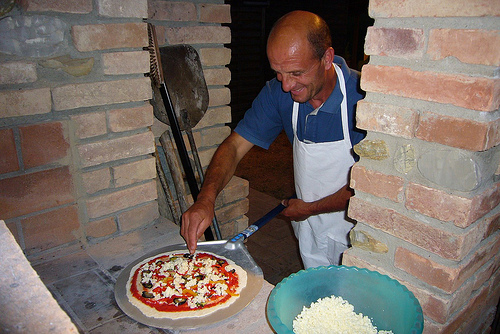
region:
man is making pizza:
[196, 29, 393, 321]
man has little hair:
[245, 10, 395, 87]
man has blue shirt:
[245, 87, 312, 157]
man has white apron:
[230, 62, 367, 282]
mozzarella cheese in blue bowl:
[281, 273, 398, 331]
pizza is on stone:
[135, 244, 228, 331]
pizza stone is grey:
[120, 236, 240, 332]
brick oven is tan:
[0, 10, 130, 235]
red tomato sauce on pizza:
[135, 261, 205, 332]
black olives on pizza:
[126, 243, 225, 304]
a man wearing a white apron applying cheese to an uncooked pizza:
[178, 9, 365, 264]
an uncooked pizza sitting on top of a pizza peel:
[124, 248, 249, 320]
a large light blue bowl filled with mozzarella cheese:
[266, 264, 425, 332]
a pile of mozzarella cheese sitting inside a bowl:
[292, 292, 390, 332]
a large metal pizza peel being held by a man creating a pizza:
[113, 200, 283, 329]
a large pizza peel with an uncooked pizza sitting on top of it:
[111, 205, 283, 328]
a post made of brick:
[343, 0, 498, 332]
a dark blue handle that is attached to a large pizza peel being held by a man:
[254, 196, 299, 228]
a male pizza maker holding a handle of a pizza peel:
[178, 9, 361, 266]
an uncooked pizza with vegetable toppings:
[127, 247, 248, 318]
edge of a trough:
[272, 280, 306, 316]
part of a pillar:
[387, 182, 438, 248]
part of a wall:
[28, 170, 85, 244]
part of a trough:
[327, 252, 368, 294]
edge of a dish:
[215, 297, 240, 324]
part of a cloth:
[304, 227, 324, 253]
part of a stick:
[168, 160, 188, 187]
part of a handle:
[242, 185, 289, 245]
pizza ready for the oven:
[121, 230, 244, 332]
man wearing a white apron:
[259, 13, 354, 230]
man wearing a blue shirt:
[227, 11, 367, 156]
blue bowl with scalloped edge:
[254, 254, 432, 330]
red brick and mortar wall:
[366, 44, 480, 239]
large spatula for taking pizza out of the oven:
[145, 41, 214, 133]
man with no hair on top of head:
[254, 10, 333, 105]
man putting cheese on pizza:
[137, 7, 338, 292]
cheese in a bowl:
[291, 296, 370, 333]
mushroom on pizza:
[140, 289, 154, 297]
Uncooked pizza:
[114, 236, 263, 332]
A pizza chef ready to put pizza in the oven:
[110, 12, 372, 312]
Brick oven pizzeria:
[16, 5, 491, 331]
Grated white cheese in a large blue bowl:
[258, 245, 448, 332]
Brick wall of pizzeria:
[0, 27, 139, 163]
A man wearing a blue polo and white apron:
[186, 10, 367, 249]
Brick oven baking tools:
[125, 15, 261, 232]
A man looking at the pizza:
[113, 6, 358, 308]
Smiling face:
[234, 7, 354, 135]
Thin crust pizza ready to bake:
[96, 227, 268, 327]